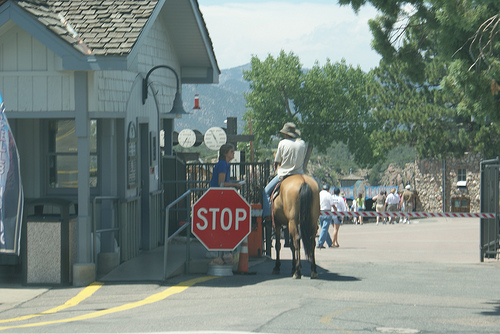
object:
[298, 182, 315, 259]
black tail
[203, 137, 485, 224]
wall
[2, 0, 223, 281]
structure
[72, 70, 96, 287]
pole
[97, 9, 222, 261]
building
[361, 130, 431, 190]
ground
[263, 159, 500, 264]
gate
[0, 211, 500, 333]
road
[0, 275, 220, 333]
lines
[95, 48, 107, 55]
shingle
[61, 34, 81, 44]
shingle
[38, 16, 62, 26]
shingle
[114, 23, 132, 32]
shingle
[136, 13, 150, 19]
shingle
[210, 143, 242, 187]
woman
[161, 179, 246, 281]
fence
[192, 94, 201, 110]
feeder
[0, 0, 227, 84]
roof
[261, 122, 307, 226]
man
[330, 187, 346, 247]
people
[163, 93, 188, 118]
light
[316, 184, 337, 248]
peole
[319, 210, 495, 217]
barrier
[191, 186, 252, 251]
sign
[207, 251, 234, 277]
pole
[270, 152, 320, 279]
horse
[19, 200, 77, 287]
trash can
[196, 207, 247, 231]
stop